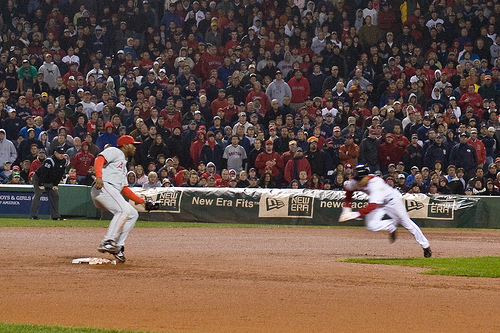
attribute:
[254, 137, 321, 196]
red jackets — red 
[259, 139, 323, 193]
sweatshirts — red 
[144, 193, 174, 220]
glove — black , leather 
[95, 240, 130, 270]
cleats — black 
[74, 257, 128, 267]
base — white, canvas 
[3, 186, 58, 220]
advertising banner — blue  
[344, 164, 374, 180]
helmet — Black 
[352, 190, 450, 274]
pants — White 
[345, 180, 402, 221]
white jersey — White 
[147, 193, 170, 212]
glove — Dark colored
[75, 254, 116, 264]
base — White 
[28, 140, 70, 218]
dark clothing — dark 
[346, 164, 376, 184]
helmet — black 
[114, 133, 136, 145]
hat — red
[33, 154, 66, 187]
jacket — black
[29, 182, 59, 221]
pants — gray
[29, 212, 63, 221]
shoes — black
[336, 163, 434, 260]
baseball player — running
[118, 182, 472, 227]
banner — advertisement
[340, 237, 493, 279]
grass — green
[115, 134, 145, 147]
cap — red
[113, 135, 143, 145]
hat — red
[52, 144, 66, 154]
hat — black 